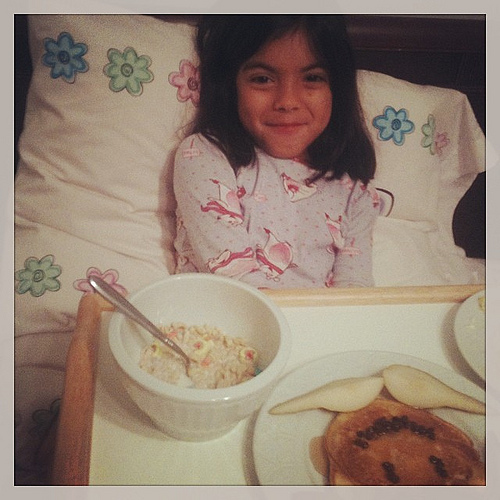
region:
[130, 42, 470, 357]
the girl is lying down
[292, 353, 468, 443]
a pear is cut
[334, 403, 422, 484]
chocolate chips on the pancakes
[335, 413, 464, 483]
the chips are on the pancake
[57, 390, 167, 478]
the tray is made of wood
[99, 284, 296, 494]
oatmeal is in the bowl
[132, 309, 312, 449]
fruit is in the bowl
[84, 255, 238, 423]
the spoon is silver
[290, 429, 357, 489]
syrup is on the plate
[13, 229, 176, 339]
flowers are on the pillow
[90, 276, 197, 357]
Top part of grey spoon in bowl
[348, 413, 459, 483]
Smiley face on pancake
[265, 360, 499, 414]
Fruit slices on the plate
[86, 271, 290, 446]
A bowl of oatmeal.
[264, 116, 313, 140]
Little girls lips forming a smile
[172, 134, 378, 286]
Little girl's pink pajamas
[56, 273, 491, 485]
Trey of assorted breakfst items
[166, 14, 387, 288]
Little girl laying down smiling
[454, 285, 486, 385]
Corner of plate on the right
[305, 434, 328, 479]
Syrup on the side of plate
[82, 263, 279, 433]
white bowl on the tray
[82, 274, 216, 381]
spoon in the white bowl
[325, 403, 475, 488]
pancakes on the plate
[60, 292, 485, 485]
white tray with wood frame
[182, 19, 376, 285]
girl sitting in bed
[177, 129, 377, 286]
pajamas the girl is wearing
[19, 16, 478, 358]
pillowcase with flower border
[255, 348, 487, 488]
plate the pancakes are on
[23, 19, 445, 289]
pillow the girl is leaning against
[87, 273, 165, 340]
handle of the spoon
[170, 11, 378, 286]
smiling girl with long dark hair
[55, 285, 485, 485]
wood tray with food on it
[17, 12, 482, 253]
pillows with flower design behind the girl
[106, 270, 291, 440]
white bowl with food in it on tray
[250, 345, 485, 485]
white plate with fruit and pancake on it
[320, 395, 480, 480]
a happy face on the pancake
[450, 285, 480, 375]
part of a white plate on the tray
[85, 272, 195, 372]
eating utensil in the white bowl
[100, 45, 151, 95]
green flower on the pillow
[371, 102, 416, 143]
blue flower on the pillow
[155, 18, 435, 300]
she is in bed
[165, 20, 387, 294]
she is leaning on her pillow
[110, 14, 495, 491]
she is eating in bed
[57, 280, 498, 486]
the food is on a tray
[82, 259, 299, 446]
this is a bowl of cereal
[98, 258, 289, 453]
the bowl is white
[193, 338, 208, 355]
there are colorful marshmallows in the bowl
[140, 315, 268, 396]
the cereal is in milk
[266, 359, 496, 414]
this is sliced pear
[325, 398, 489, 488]
a chocolate chip pancake with a smiley face